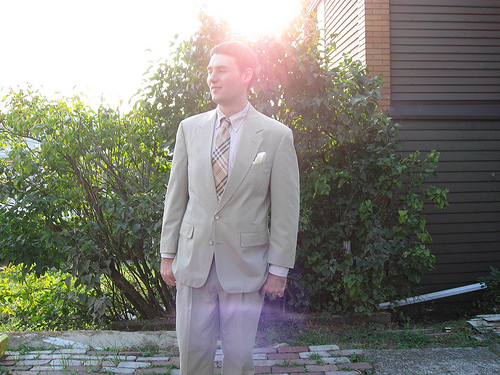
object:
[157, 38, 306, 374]
man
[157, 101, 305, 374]
suit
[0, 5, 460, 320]
trees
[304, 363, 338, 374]
brick sidewalk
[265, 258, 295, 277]
jacket sleeve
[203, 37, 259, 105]
head looking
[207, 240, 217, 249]
bottom button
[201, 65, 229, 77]
2 eyes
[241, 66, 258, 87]
left ear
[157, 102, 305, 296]
suit coat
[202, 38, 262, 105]
head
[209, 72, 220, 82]
nose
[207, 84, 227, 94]
mouth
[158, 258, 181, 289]
right hand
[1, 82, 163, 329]
green yard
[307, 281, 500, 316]
hand rail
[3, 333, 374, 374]
walkway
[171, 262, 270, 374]
beige pants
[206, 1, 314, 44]
bright sun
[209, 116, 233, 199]
plaid tie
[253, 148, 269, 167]
white handkerchief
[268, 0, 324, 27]
rain gutter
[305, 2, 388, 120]
side of house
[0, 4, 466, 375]
bush in yard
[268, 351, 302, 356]
bricks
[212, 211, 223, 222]
button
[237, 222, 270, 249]
pocket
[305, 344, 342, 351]
brick pathway